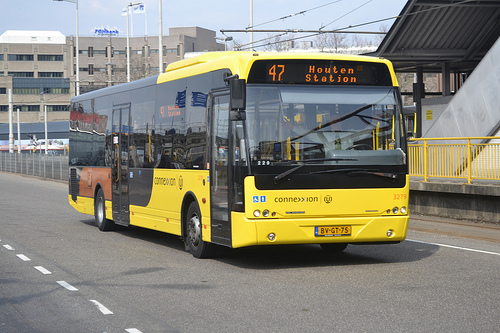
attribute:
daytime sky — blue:
[3, 0, 400, 48]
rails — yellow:
[406, 136, 499, 183]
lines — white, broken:
[7, 245, 108, 330]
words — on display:
[246, 57, 398, 93]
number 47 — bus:
[258, 50, 292, 87]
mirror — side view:
[228, 77, 246, 109]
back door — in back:
[111, 101, 130, 227]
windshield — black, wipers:
[243, 78, 414, 173]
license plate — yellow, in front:
[307, 217, 365, 239]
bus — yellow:
[52, 43, 412, 255]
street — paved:
[4, 170, 484, 330]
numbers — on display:
[263, 60, 293, 89]